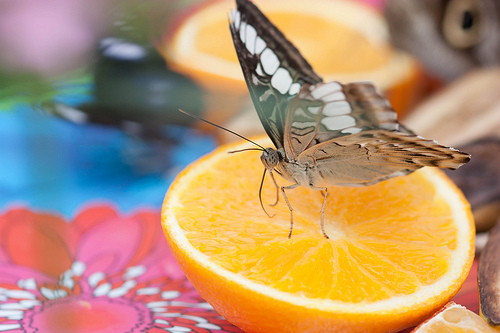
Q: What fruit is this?
A: Orange.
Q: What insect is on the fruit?
A: Butterfly.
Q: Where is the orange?
A: Floral cloth.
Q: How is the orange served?
A: Halved.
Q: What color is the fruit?
A: Orange.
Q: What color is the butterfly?
A: Silver and black.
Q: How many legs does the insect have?
A: 4.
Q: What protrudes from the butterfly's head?
A: Antenna.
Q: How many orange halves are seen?
A: 2.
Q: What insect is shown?
A: Butterfly.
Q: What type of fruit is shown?
A: Oranges.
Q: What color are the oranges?
A: Orange.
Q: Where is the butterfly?
A: On the orange.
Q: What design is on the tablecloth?
A: Floral.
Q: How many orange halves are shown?
A: 2.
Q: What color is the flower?
A: Red, pink, and white.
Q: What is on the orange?
A: A butterfly.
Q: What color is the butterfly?
A: Brown and white.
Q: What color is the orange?
A: Orange and white.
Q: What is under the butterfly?
A: An orange.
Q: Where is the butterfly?
A: On the orange.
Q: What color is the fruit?
A: Orange.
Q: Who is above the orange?
A: The butterfly.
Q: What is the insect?
A: A butterfly.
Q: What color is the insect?
A: Brown and white.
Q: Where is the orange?
A: Below the insect.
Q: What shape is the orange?
A: A circle.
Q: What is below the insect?
A: An orange.